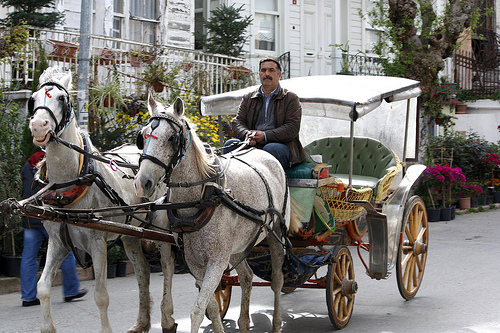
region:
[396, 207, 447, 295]
yellow spokes on round wheel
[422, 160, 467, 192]
purple flowers in pot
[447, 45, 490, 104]
large brown iron gate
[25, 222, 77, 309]
man wearing light color blue jeans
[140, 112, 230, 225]
black rein on horse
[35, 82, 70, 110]
red spot on horse's face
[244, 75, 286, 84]
black mustache on man's face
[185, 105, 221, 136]
cluster of bright yellow flowers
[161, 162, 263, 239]
black and brown harness around horse's neck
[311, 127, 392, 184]
green felt seat in carraige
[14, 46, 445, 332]
Horse cart on street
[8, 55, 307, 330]
Two horses pulling a cart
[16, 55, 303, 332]
Horses are white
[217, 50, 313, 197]
Man holding straps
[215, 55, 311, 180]
Man wearing brown jacket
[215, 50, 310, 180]
Man wearing blue jeans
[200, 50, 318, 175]
Man sits on a horse cart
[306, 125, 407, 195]
Sit of cart is green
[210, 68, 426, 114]
Roof of cart is white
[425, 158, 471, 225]
Pots with purple flowers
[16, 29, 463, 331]
Horse drawn cart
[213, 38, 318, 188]
Man sitting on carriage holding straps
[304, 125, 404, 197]
Carriage sit is green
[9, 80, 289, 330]
Two horses pulling a carriage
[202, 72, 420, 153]
Carriage roof is white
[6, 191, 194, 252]
Pole in front of horses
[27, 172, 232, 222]
Strap holding the pole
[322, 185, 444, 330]
Wheels of carriage are orange and black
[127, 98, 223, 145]
Yellow flowers behind the carriage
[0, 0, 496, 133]
White building on background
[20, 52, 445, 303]
driver on carriage pulled by horses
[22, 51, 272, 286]
horses in harnesses around heads and bodies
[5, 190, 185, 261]
connective rod in front of both horses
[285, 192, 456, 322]
carriage wheels in different sizes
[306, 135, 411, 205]
tufted passenger seat in green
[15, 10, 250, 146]
white railing to side of horses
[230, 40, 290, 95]
serious face on moustached driver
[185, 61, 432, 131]
white canopy with side panels rolled up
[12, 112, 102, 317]
person walking behind the horses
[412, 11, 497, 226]
flowers and tree behind the carriage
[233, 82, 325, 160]
the jacket is brown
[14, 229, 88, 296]
the trousers are blue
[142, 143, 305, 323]
the horse is spotted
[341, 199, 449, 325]
the wheels are orange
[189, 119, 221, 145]
the flowers are yellow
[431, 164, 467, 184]
the flowers are red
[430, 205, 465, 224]
the vase is black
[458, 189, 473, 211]
the vase is brown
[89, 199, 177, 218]
the ropes are black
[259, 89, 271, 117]
the shirt is blue